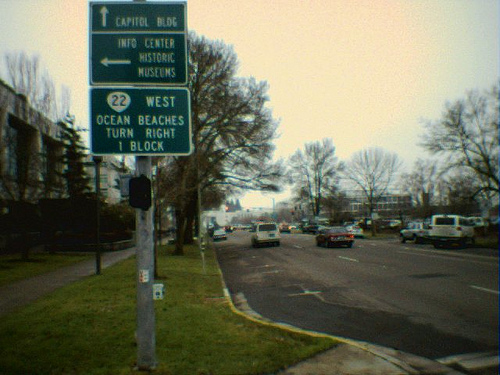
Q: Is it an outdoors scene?
A: Yes, it is outdoors.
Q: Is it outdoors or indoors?
A: It is outdoors.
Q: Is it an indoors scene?
A: No, it is outdoors.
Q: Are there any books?
A: No, there are no books.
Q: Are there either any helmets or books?
A: No, there are no books or helmets.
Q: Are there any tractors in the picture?
A: No, there are no tractors.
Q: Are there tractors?
A: No, there are no tractors.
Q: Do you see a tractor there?
A: No, there are no tractors.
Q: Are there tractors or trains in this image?
A: No, there are no tractors or trains.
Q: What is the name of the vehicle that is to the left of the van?
A: The vehicle is a car.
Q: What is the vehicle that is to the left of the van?
A: The vehicle is a car.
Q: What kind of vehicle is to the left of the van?
A: The vehicle is a car.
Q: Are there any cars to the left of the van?
A: Yes, there is a car to the left of the van.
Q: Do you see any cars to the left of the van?
A: Yes, there is a car to the left of the van.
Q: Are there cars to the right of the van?
A: No, the car is to the left of the van.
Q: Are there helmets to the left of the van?
A: No, there is a car to the left of the van.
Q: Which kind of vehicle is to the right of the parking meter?
A: The vehicle is a car.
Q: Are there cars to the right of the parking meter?
A: Yes, there is a car to the right of the parking meter.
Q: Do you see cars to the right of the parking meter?
A: Yes, there is a car to the right of the parking meter.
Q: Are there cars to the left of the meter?
A: No, the car is to the right of the meter.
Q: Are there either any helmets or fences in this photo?
A: No, there are no fences or helmets.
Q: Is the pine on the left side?
A: Yes, the pine is on the left of the image.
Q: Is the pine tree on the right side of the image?
A: No, the pine tree is on the left of the image.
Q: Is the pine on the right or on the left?
A: The pine is on the left of the image.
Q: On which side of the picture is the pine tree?
A: The pine tree is on the left of the image.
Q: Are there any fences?
A: No, there are no fences.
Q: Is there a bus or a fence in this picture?
A: No, there are no fences or buses.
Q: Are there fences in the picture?
A: No, there are no fences.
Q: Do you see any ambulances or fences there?
A: No, there are no fences or ambulances.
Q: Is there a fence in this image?
A: No, there are no fences.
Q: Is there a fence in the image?
A: No, there are no fences.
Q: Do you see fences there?
A: No, there are no fences.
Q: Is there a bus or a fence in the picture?
A: No, there are no fences or buses.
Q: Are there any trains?
A: No, there are no trains.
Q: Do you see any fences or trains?
A: No, there are no trains or fences.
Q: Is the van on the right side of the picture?
A: Yes, the van is on the right of the image.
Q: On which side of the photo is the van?
A: The van is on the right of the image.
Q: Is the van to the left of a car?
A: No, the van is to the right of a car.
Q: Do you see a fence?
A: No, there are no fences.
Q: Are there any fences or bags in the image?
A: No, there are no fences or bags.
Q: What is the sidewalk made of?
A: The sidewalk is made of concrete.